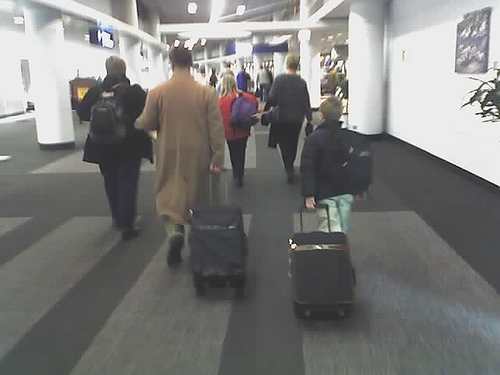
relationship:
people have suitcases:
[84, 46, 367, 247] [182, 168, 358, 319]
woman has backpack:
[217, 75, 257, 185] [223, 92, 259, 135]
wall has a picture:
[380, 1, 498, 190] [454, 7, 489, 73]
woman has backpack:
[217, 75, 257, 185] [324, 129, 372, 191]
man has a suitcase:
[140, 45, 231, 272] [191, 202, 246, 297]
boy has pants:
[303, 100, 359, 247] [319, 191, 353, 243]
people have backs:
[84, 46, 367, 247] [93, 84, 349, 180]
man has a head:
[140, 45, 231, 272] [168, 49, 194, 70]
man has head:
[140, 45, 231, 272] [168, 49, 194, 70]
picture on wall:
[454, 7, 489, 73] [380, 1, 498, 190]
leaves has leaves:
[459, 67, 499, 124] [463, 66, 499, 125]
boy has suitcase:
[303, 100, 359, 247] [191, 202, 246, 297]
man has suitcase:
[140, 45, 231, 272] [191, 202, 246, 297]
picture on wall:
[452, 14, 487, 72] [380, 1, 498, 190]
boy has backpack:
[303, 100, 359, 247] [324, 129, 372, 191]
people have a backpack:
[84, 46, 367, 247] [324, 129, 372, 191]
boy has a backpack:
[303, 100, 359, 247] [324, 129, 372, 191]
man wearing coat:
[140, 45, 231, 272] [136, 68, 229, 224]